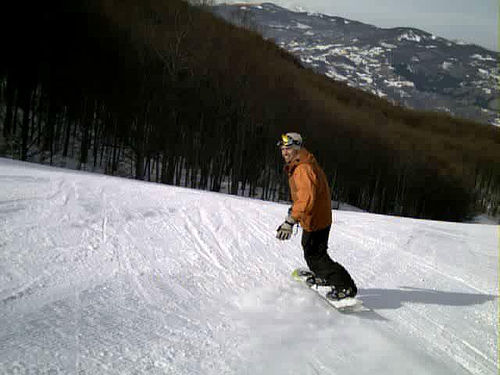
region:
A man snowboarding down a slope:
[258, 129, 377, 317]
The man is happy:
[276, 130, 308, 172]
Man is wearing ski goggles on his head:
[275, 128, 301, 163]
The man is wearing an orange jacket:
[268, 135, 342, 254]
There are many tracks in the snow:
[75, 205, 251, 335]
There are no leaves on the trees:
[85, 25, 222, 180]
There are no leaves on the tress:
[113, 67, 233, 187]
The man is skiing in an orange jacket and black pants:
[270, 126, 361, 334]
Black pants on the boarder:
[290, 198, 363, 323]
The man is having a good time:
[237, 112, 334, 197]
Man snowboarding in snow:
[276, 132, 358, 317]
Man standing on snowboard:
[276, 135, 368, 312]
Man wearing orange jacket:
[279, 134, 333, 229]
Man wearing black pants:
[299, 230, 361, 299]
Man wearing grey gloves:
[277, 213, 292, 243]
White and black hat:
[279, 128, 300, 150]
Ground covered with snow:
[1, 164, 498, 373]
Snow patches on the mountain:
[238, 3, 498, 115]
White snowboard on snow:
[305, 263, 362, 318]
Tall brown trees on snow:
[0, 0, 498, 222]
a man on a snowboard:
[252, 100, 419, 331]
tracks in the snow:
[111, 232, 228, 324]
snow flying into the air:
[266, 297, 303, 329]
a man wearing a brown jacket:
[268, 113, 380, 338]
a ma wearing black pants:
[250, 114, 368, 331]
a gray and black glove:
[271, 212, 301, 234]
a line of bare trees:
[40, 55, 280, 175]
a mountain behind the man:
[286, 14, 482, 91]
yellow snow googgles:
[280, 127, 297, 142]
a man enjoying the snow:
[264, 119, 389, 359]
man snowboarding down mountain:
[255, 128, 359, 323]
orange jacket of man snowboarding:
[284, 160, 328, 230]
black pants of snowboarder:
[298, 234, 354, 297]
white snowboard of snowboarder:
[308, 277, 360, 309]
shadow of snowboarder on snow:
[346, 271, 494, 313]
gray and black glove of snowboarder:
[280, 218, 294, 238]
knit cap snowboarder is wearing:
[274, 135, 303, 145]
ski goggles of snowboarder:
[276, 135, 298, 150]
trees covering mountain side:
[9, 13, 490, 198]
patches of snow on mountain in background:
[263, 3, 498, 128]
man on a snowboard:
[267, 130, 372, 317]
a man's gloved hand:
[276, 216, 295, 241]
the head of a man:
[275, 131, 301, 161]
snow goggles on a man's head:
[278, 132, 292, 144]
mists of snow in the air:
[236, 285, 417, 373]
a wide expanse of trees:
[0, 2, 498, 216]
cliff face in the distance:
[202, 0, 498, 130]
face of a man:
[280, 145, 294, 162]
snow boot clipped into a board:
[324, 283, 355, 300]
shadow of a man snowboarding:
[352, 279, 499, 317]